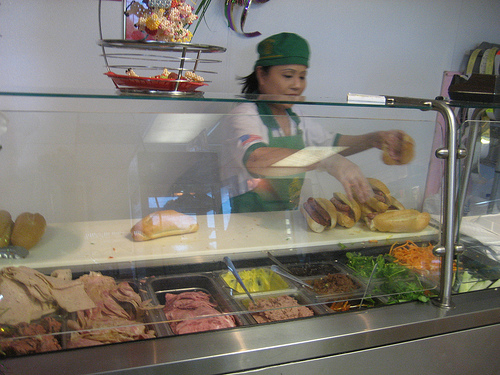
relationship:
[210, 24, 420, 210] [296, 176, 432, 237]
woman making sandwiches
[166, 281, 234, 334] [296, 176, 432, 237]
meat for sandwiches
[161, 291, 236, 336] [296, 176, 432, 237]
meat for sandwiches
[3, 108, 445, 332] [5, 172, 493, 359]
plastic covering food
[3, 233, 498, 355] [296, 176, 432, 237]
garnishes for sandwiches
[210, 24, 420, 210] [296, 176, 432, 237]
woman stacking sandwiches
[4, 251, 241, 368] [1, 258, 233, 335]
containers with deli meat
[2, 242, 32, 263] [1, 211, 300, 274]
tongs sitting on counter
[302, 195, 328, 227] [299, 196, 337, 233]
sandwich with sandwich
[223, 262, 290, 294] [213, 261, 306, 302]
mayonaise in tub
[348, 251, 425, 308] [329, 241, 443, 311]
lettuce in tub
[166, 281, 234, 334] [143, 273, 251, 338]
meat in containers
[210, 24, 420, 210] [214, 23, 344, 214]
woman wearing green and white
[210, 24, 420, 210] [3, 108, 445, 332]
woman behind glass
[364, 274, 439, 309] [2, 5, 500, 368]
vegetables in kitchen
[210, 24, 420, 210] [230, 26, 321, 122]
person has head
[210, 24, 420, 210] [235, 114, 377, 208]
person has arm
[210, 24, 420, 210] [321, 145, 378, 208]
person has hand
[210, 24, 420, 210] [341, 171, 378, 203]
person has fingers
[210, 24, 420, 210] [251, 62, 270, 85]
person has ear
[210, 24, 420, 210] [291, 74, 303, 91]
woman has nose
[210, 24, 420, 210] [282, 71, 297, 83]
woman has eye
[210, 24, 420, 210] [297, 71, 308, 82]
woman has eye